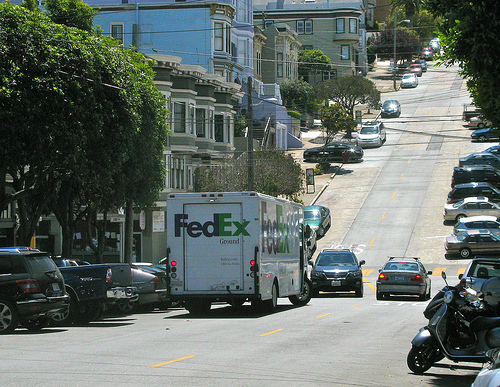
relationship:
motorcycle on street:
[408, 275, 495, 373] [33, 70, 485, 387]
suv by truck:
[306, 247, 367, 296] [167, 191, 312, 314]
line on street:
[258, 325, 283, 339] [33, 70, 485, 387]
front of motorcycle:
[405, 328, 440, 371] [408, 275, 495, 373]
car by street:
[443, 197, 500, 224] [33, 70, 485, 387]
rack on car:
[388, 253, 418, 261] [376, 256, 433, 301]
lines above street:
[126, 32, 454, 77] [33, 70, 485, 387]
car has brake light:
[376, 256, 433, 301] [380, 273, 385, 283]